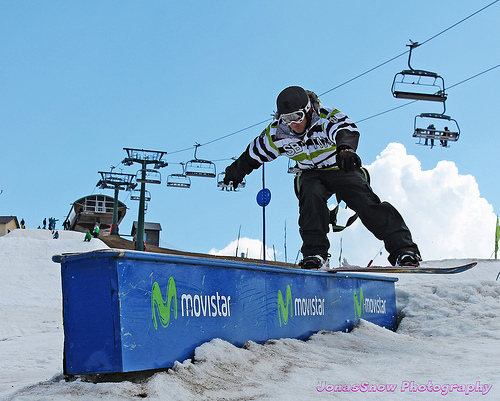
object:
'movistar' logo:
[179, 288, 236, 322]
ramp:
[48, 244, 405, 377]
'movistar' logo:
[146, 272, 183, 334]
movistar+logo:
[142, 269, 236, 336]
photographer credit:
[310, 373, 493, 397]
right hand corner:
[309, 371, 499, 399]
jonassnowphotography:
[319, 379, 492, 396]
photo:
[2, 0, 498, 399]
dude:
[202, 73, 482, 278]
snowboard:
[319, 258, 481, 280]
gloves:
[221, 155, 253, 188]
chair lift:
[387, 36, 450, 104]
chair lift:
[409, 102, 476, 153]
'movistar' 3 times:
[136, 275, 391, 320]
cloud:
[421, 157, 497, 259]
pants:
[293, 168, 420, 261]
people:
[17, 210, 66, 240]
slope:
[0, 229, 49, 401]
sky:
[2, 1, 245, 124]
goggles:
[274, 97, 308, 128]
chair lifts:
[184, 147, 216, 180]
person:
[438, 124, 452, 150]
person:
[417, 124, 436, 150]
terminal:
[62, 188, 131, 239]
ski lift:
[92, 1, 498, 198]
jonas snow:
[313, 377, 398, 396]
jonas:
[312, 377, 358, 397]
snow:
[360, 327, 500, 379]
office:
[128, 219, 163, 251]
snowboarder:
[213, 83, 423, 273]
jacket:
[231, 105, 361, 179]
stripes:
[243, 111, 355, 184]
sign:
[254, 183, 276, 209]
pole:
[259, 152, 267, 263]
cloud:
[211, 230, 278, 254]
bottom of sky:
[194, 109, 497, 267]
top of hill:
[1, 231, 500, 401]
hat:
[270, 77, 310, 115]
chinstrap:
[288, 129, 313, 138]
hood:
[305, 87, 324, 115]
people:
[415, 121, 461, 147]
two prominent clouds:
[201, 113, 498, 263]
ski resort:
[0, 178, 206, 273]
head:
[272, 82, 315, 136]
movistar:
[269, 283, 332, 329]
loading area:
[15, 207, 109, 244]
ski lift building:
[0, 209, 22, 240]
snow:
[0, 336, 54, 383]